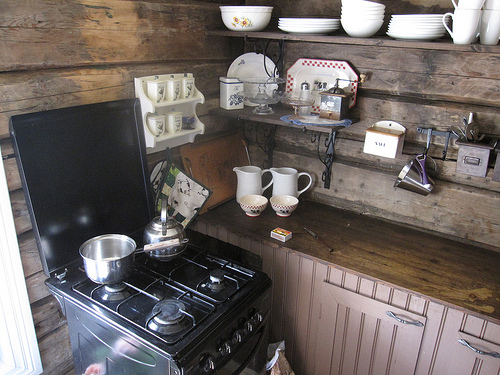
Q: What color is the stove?
A: Black.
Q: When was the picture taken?
A: Daytime.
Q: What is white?
A: Two pitchers.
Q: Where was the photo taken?
A: In a kitchen.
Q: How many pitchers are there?
A: Two.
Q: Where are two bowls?
A: On the countertop.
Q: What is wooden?
A: The walls.